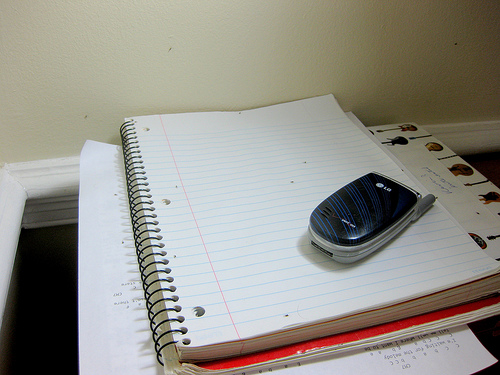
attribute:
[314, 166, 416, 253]
cellphone — old, wireless, grey, blue, silver, shiny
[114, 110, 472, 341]
notebook — open, red, orange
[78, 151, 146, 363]
sheet — white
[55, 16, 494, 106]
wall — tan, white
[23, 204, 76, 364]
surface — glass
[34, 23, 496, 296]
picture — indoor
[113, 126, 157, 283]
spiral — black, silver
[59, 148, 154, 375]
paper — white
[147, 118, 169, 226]
holes — small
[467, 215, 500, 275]
stamp — postage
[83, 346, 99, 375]
spot — white, black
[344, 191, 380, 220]
lines — blue, black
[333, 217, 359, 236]
words — white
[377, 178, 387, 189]
circle — small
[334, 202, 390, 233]
stripes — blue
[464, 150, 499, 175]
floor — brown, wood